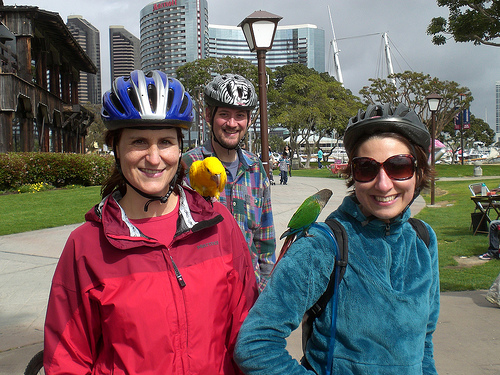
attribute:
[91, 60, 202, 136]
helmet — blue, silver, white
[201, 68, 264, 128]
helmet — grey, black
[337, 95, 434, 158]
helmet — gray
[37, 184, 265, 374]
jacket — pink, red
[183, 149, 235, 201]
bird — yellow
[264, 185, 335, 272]
bird — green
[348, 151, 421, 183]
sunglasses — big, brown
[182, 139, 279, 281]
shirt — checkered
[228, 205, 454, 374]
jacket — blue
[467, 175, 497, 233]
chair — metal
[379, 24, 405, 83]
mast — white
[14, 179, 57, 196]
flowers — yellow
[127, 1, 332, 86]
building — silver